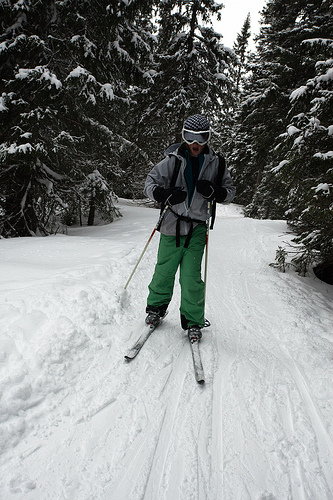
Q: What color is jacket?
A: Black and gray.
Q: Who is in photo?
A: Man in goggles skiing thru snow.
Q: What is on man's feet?
A: Snow covered skis.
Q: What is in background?
A: Large cluster of tall green trees.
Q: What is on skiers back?
A: Backpack.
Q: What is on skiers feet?
A: Snow skis.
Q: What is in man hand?
A: Ski pole.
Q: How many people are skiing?
A: One.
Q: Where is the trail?
A: Between the trees.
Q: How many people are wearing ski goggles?
A: One.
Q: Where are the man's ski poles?
A: In his hands.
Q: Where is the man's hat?
A: On his head.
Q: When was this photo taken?
A: During the daytime.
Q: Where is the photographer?
A: In front of the skier.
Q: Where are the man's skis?
A: On the snow.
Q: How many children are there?
A: Zero.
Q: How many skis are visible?
A: 2.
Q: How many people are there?
A: 1.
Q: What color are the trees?
A: Green.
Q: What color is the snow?
A: White.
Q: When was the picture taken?
A: Daytime.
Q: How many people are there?
A: One.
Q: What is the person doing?
A: Skiing.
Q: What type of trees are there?
A: Pine trees.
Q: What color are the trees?
A: Green.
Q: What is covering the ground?
A: Snow.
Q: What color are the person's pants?
A: Green.